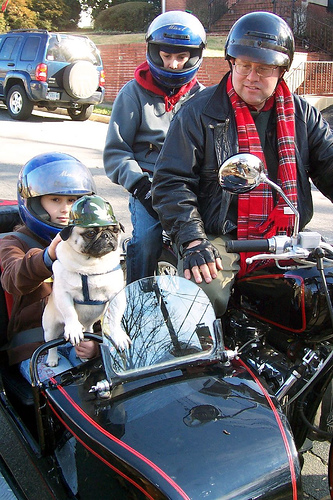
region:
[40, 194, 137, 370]
pug in a sidecar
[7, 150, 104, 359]
kid in side car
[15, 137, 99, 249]
kid wearing helmet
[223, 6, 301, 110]
man wearing helmet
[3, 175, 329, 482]
black and red motorcycle with sidecar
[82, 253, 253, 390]
windshield on sidecar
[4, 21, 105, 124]
blue SUV in background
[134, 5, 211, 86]
guy wearing blue helmet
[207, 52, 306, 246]
guy wearing red plaid scarf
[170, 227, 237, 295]
guy wearing fingerless gloves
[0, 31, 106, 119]
Blue jeep parked on side of road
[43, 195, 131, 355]
Pug wearing green helmet and blue harness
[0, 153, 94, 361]
Boy wearing blue helmet holding dog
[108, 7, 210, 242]
Boy wearing blue helmet and grey sweater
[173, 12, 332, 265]
Man wearing black helmet and black leather jacket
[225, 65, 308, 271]
Red scarf draped around neck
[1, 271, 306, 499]
Black polished motorcycle side car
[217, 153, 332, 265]
Chrome motorcycle rear view mirror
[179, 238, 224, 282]
Black leather fingerless glove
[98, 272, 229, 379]
Side car wind shield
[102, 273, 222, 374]
curved windshield of a sidecar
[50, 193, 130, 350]
small dog wearing a camoflage helmet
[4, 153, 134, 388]
boy and his dog riding in a sidecar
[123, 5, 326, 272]
two people on a motercycle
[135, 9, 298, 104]
two people wearinghelmets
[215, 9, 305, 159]
man in a helmet wearing a plaid scarf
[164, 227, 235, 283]
man wearing fingerless gloves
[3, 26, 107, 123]
parked vehicle on the street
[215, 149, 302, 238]
silver motorcycle side mirror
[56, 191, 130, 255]
pug in a helmet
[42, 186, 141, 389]
A PUG WEARING A CAMOFLAGED HAT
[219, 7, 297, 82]
A BLACK MOTORCYCLE HELMET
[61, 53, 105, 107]
A SPARE TIRE IN A LEATHER CASE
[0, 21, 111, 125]
A BLUE SUV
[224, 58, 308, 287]
A RED, WHITE, AND GREEN SCARF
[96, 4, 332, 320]
TWO PEOPLE ON ONE MOTORCYCLE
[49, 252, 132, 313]
A HARNESS FOR DOGS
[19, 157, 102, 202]
A CLEAR HELMET VISOR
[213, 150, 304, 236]
A MOTORCYCLE'S REAR VIEW MIRROS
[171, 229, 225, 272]
A LEATHER, FINGERLESS GLOVE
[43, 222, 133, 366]
a pug dog on the boy's lap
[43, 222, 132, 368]
a dog is in the boy's lap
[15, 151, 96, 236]
a blue motorcycle helmet is on the boy's head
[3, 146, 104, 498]
a boy is sitting in the motorcycle sidecar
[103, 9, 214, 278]
a boy is sitting behind the driver of the motorcyle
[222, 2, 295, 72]
a black helmet is on the driver's head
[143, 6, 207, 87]
a blue helmet is on the passenger's head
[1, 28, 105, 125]
a car is behind the motorcycle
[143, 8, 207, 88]
a blue car is behind the motorcycle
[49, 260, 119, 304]
a harness is on the pug